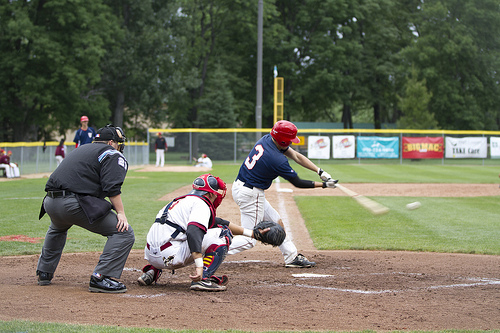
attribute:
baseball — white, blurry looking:
[405, 199, 422, 214]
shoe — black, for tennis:
[289, 249, 318, 274]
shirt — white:
[142, 192, 213, 247]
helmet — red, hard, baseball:
[269, 120, 301, 144]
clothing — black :
[43, 140, 130, 267]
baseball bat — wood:
[329, 178, 386, 215]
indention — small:
[235, 290, 293, 312]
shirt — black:
[233, 129, 319, 193]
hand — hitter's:
[318, 179, 333, 188]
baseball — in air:
[396, 194, 433, 222]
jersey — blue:
[237, 135, 296, 190]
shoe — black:
[283, 252, 315, 270]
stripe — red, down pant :
[253, 189, 263, 228]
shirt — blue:
[228, 131, 340, 205]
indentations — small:
[85, 294, 116, 304]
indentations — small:
[129, 308, 166, 319]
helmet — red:
[270, 122, 299, 151]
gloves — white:
[315, 168, 340, 187]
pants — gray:
[36, 190, 135, 280]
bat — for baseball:
[332, 182, 389, 224]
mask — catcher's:
[212, 177, 228, 207]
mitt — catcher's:
[248, 212, 289, 247]